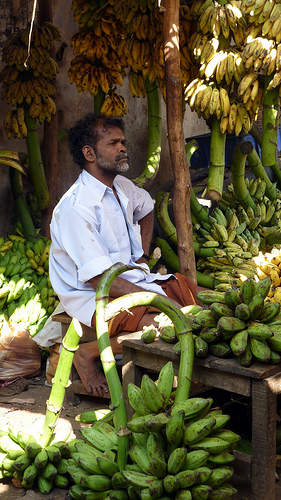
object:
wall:
[54, 92, 73, 140]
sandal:
[75, 409, 114, 424]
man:
[48, 113, 183, 397]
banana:
[214, 223, 228, 243]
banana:
[249, 293, 265, 320]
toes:
[100, 383, 109, 393]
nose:
[116, 142, 127, 152]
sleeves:
[61, 206, 113, 286]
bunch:
[67, 64, 124, 97]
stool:
[46, 312, 112, 400]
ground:
[0, 373, 41, 451]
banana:
[209, 88, 219, 115]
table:
[116, 328, 281, 498]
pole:
[164, 0, 197, 301]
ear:
[82, 145, 95, 163]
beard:
[97, 153, 130, 176]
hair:
[63, 112, 126, 170]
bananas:
[195, 289, 225, 305]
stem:
[95, 261, 195, 473]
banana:
[166, 410, 186, 449]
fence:
[48, 169, 154, 329]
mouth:
[115, 153, 129, 165]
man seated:
[51, 312, 123, 406]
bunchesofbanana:
[0, 0, 281, 137]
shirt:
[48, 168, 178, 328]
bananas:
[101, 96, 112, 114]